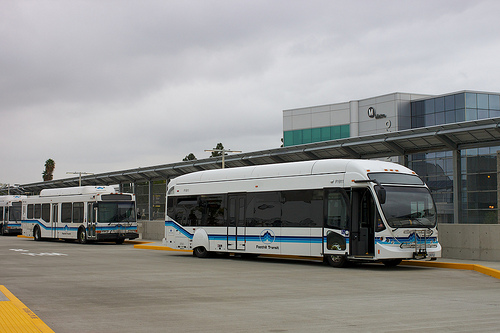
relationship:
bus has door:
[174, 149, 411, 260] [343, 190, 381, 264]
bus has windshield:
[174, 149, 411, 260] [376, 185, 431, 236]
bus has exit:
[174, 149, 411, 260] [224, 192, 244, 255]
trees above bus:
[178, 135, 226, 163] [174, 149, 411, 260]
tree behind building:
[40, 157, 58, 178] [286, 91, 491, 147]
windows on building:
[415, 87, 500, 138] [286, 91, 491, 147]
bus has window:
[174, 149, 411, 260] [376, 185, 431, 236]